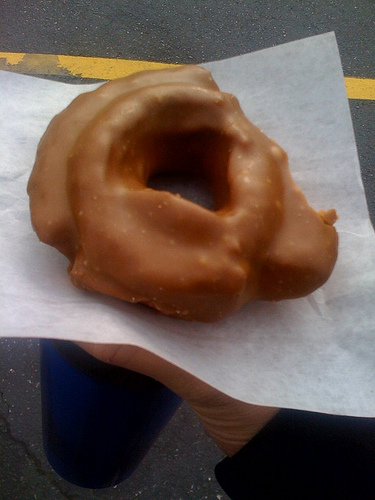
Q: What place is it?
A: It is a road.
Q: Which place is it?
A: It is a road.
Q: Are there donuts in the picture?
A: Yes, there is a donut.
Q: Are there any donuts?
A: Yes, there is a donut.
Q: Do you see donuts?
A: Yes, there is a donut.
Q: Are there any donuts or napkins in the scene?
A: Yes, there is a donut.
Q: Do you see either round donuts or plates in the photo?
A: Yes, there is a round donut.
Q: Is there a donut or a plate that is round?
A: Yes, the donut is round.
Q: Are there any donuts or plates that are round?
A: Yes, the donut is round.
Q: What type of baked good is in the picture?
A: The baked good is a donut.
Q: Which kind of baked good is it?
A: The food is a donut.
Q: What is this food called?
A: That is a donut.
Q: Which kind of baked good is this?
A: That is a donut.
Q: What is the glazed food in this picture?
A: The food is a donut.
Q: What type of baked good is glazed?
A: The baked good is a donut.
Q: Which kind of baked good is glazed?
A: The baked good is a donut.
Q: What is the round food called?
A: The food is a donut.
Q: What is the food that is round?
A: The food is a donut.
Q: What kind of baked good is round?
A: The baked good is a donut.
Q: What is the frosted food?
A: The food is a donut.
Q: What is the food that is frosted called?
A: The food is a donut.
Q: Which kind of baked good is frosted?
A: The baked good is a donut.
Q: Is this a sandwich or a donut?
A: This is a donut.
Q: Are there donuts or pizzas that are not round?
A: No, there is a donut but it is round.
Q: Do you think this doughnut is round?
A: Yes, the doughnut is round.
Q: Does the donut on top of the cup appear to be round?
A: Yes, the doughnut is round.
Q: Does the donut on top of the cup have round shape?
A: Yes, the doughnut is round.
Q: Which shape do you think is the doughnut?
A: The doughnut is round.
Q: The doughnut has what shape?
A: The doughnut is round.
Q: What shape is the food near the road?
A: The doughnut is round.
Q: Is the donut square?
A: No, the donut is round.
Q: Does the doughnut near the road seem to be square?
A: No, the doughnut is round.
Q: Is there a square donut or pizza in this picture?
A: No, there is a donut but it is round.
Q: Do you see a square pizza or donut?
A: No, there is a donut but it is round.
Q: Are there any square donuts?
A: No, there is a donut but it is round.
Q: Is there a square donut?
A: No, there is a donut but it is round.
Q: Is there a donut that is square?
A: No, there is a donut but it is round.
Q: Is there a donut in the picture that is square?
A: No, there is a donut but it is round.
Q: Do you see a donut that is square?
A: No, there is a donut but it is round.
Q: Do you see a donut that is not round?
A: No, there is a donut but it is round.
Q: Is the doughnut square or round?
A: The doughnut is round.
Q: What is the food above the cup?
A: The food is a donut.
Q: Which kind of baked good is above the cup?
A: The food is a donut.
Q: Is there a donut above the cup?
A: Yes, there is a donut above the cup.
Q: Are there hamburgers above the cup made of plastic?
A: No, there is a donut above the cup.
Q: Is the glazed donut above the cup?
A: Yes, the donut is above the cup.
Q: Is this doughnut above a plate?
A: No, the doughnut is above the cup.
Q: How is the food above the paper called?
A: The food is a donut.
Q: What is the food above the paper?
A: The food is a donut.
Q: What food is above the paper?
A: The food is a donut.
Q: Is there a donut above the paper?
A: Yes, there is a donut above the paper.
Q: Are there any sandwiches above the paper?
A: No, there is a donut above the paper.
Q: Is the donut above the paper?
A: Yes, the donut is above the paper.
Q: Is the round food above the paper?
A: Yes, the donut is above the paper.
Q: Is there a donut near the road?
A: Yes, there is a donut near the road.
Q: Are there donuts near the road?
A: Yes, there is a donut near the road.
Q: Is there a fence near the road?
A: No, there is a donut near the road.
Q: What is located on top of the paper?
A: The donut is on top of the paper.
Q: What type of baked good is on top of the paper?
A: The food is a donut.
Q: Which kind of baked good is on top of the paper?
A: The food is a donut.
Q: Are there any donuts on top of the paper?
A: Yes, there is a donut on top of the paper.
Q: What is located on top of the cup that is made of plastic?
A: The doughnut is on top of the cup.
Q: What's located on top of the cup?
A: The doughnut is on top of the cup.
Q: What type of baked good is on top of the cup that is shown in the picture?
A: The food is a donut.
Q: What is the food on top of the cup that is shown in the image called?
A: The food is a donut.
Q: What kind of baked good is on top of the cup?
A: The food is a donut.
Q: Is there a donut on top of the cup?
A: Yes, there is a donut on top of the cup.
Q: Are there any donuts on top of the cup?
A: Yes, there is a donut on top of the cup.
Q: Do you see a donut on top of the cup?
A: Yes, there is a donut on top of the cup.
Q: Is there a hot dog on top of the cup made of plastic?
A: No, there is a donut on top of the cup.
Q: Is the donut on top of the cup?
A: Yes, the donut is on top of the cup.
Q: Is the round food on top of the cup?
A: Yes, the donut is on top of the cup.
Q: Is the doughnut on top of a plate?
A: No, the doughnut is on top of the cup.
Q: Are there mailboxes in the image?
A: No, there are no mailboxes.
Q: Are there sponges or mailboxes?
A: No, there are no mailboxes or sponges.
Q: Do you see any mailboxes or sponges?
A: No, there are no mailboxes or sponges.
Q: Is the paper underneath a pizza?
A: No, the paper is underneath the doughnut.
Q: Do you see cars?
A: No, there are no cars.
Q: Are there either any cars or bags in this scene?
A: No, there are no cars or bags.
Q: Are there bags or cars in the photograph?
A: No, there are no cars or bags.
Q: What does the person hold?
A: The person holds the donut.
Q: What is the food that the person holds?
A: The food is a donut.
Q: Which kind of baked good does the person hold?
A: The person holds the doughnut.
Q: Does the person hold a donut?
A: Yes, the person holds a donut.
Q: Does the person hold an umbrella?
A: No, the person holds a donut.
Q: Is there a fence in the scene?
A: No, there are no fences.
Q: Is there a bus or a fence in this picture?
A: No, there are no fences or buses.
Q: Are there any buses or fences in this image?
A: No, there are no fences or buses.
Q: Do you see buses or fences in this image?
A: No, there are no fences or buses.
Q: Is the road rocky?
A: Yes, the road is rocky.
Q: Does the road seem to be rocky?
A: Yes, the road is rocky.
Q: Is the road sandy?
A: No, the road is rocky.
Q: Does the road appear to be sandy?
A: No, the road is rocky.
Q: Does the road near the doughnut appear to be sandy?
A: No, the road is rocky.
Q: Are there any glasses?
A: No, there are no glasses.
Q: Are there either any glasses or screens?
A: No, there are no glasses or screens.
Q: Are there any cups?
A: Yes, there is a cup.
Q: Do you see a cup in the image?
A: Yes, there is a cup.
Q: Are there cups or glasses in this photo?
A: Yes, there is a cup.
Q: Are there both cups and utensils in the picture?
A: No, there is a cup but no utensils.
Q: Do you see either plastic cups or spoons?
A: Yes, there is a plastic cup.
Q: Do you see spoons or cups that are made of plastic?
A: Yes, the cup is made of plastic.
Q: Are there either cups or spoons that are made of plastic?
A: Yes, the cup is made of plastic.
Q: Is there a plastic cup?
A: Yes, there is a cup that is made of plastic.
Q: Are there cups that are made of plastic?
A: Yes, there is a cup that is made of plastic.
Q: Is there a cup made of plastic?
A: Yes, there is a cup that is made of plastic.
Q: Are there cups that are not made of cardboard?
A: Yes, there is a cup that is made of plastic.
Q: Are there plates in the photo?
A: No, there are no plates.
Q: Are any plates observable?
A: No, there are no plates.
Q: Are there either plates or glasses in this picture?
A: No, there are no plates or glasses.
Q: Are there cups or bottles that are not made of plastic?
A: No, there is a cup but it is made of plastic.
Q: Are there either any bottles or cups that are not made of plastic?
A: No, there is a cup but it is made of plastic.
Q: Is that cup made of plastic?
A: Yes, the cup is made of plastic.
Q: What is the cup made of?
A: The cup is made of plastic.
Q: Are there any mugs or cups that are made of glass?
A: No, there is a cup but it is made of plastic.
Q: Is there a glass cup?
A: No, there is a cup but it is made of plastic.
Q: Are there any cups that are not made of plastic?
A: No, there is a cup but it is made of plastic.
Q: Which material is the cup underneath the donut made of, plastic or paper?
A: The cup is made of plastic.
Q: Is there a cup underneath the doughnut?
A: Yes, there is a cup underneath the doughnut.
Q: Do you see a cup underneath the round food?
A: Yes, there is a cup underneath the doughnut.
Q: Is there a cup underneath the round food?
A: Yes, there is a cup underneath the doughnut.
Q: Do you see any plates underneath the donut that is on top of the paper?
A: No, there is a cup underneath the doughnut.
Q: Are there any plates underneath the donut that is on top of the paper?
A: No, there is a cup underneath the doughnut.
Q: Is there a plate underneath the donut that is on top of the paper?
A: No, there is a cup underneath the doughnut.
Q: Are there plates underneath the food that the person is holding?
A: No, there is a cup underneath the doughnut.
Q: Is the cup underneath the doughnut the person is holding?
A: Yes, the cup is underneath the doughnut.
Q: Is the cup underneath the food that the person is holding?
A: Yes, the cup is underneath the doughnut.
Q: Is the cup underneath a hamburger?
A: No, the cup is underneath the doughnut.